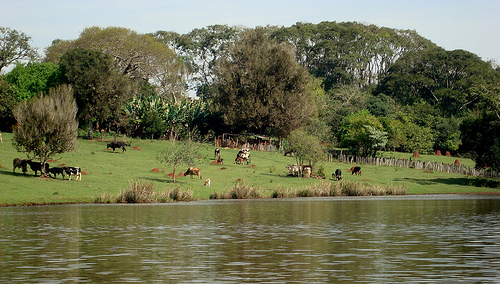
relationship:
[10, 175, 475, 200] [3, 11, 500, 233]
shoreline in country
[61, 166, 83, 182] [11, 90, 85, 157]
cow under tree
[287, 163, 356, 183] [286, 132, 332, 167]
holsteins under tree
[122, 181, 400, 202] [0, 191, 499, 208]
grass along shoreline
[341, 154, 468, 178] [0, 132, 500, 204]
fence separates grass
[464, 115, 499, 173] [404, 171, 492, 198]
tree has shadow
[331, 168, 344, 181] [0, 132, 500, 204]
cows in grass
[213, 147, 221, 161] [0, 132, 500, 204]
cow in grass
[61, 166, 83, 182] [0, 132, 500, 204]
cow in grass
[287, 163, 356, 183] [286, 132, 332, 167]
cows under tree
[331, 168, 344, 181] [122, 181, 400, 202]
cows eat grass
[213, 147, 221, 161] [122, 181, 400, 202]
cow eat grass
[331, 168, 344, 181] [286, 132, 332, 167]
cows near tree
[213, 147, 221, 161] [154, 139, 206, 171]
cow near tree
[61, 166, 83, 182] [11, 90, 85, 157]
cow near tree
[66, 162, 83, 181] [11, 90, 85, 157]
cow under tree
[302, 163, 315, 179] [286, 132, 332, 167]
cow under tree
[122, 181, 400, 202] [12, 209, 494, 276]
grass next to water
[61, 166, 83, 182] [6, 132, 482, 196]
cow in field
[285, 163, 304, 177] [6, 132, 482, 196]
cow in field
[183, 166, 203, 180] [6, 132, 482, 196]
cow in field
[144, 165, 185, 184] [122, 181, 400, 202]
piles on grass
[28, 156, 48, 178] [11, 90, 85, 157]
cow under tree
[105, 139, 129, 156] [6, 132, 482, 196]
cow in field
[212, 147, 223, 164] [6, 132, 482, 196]
cow in field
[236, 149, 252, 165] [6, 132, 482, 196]
cow in field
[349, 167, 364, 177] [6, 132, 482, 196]
cow in field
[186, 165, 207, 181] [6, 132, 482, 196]
cow in field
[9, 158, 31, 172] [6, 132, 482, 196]
cow in field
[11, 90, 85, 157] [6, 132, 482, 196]
tree in field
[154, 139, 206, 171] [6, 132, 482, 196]
tree in field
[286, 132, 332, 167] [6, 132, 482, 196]
tree in field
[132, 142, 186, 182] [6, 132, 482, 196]
haystacks in field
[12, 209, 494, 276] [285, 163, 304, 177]
pond in front of cow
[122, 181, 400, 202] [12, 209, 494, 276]
grass behind pond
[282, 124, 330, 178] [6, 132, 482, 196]
trees in field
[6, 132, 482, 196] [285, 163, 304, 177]
field has cow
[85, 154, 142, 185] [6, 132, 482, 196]
grass in field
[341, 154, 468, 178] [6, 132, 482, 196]
fence next to field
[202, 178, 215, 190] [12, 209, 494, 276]
calf near pond